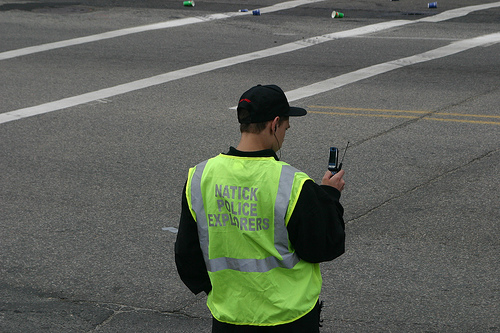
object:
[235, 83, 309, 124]
hat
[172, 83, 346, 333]
man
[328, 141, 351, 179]
phone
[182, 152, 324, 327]
vest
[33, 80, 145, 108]
line